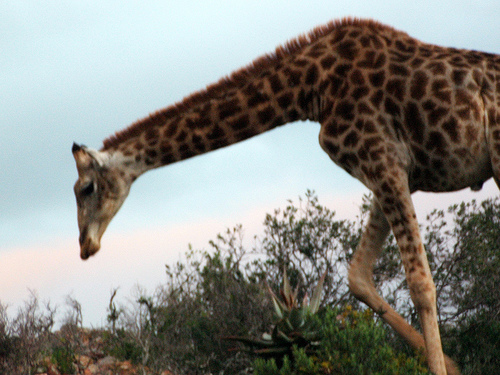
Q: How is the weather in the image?
A: It is cloudy.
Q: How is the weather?
A: It is cloudy.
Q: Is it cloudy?
A: Yes, it is cloudy.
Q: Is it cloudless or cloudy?
A: It is cloudy.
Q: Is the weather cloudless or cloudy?
A: It is cloudy.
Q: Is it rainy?
A: No, it is cloudy.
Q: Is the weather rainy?
A: No, it is cloudy.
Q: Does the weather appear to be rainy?
A: No, it is cloudy.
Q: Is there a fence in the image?
A: No, there are no fences.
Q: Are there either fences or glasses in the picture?
A: No, there are no fences or glasses.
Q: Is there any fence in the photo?
A: No, there are no fences.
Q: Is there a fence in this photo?
A: No, there are no fences.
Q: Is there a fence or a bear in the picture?
A: No, there are no fences or bears.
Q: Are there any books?
A: No, there are no books.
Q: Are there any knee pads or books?
A: No, there are no books or knee pads.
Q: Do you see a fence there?
A: No, there are no fences.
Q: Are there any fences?
A: No, there are no fences.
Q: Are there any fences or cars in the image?
A: No, there are no fences or cars.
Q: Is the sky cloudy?
A: Yes, the sky is cloudy.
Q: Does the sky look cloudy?
A: Yes, the sky is cloudy.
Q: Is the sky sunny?
A: No, the sky is cloudy.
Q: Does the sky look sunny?
A: No, the sky is cloudy.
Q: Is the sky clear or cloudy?
A: The sky is cloudy.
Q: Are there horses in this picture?
A: No, there are no horses.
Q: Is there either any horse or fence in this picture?
A: No, there are no horses or fences.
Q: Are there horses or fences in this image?
A: No, there are no horses or fences.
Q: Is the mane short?
A: Yes, the mane is short.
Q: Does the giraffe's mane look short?
A: Yes, the mane is short.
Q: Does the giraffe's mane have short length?
A: Yes, the mane is short.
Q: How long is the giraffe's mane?
A: The mane is short.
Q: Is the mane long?
A: No, the mane is short.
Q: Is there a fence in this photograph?
A: No, there are no fences.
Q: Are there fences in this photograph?
A: No, there are no fences.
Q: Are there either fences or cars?
A: No, there are no fences or cars.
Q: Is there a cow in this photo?
A: No, there are no cows.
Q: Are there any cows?
A: No, there are no cows.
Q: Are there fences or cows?
A: No, there are no cows or fences.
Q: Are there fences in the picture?
A: No, there are no fences.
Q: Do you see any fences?
A: No, there are no fences.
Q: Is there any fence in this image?
A: No, there are no fences.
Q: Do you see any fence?
A: No, there are no fences.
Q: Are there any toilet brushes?
A: No, there are no toilet brushes.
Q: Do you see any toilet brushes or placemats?
A: No, there are no toilet brushes or placemats.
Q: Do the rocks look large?
A: Yes, the rocks are large.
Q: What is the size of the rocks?
A: The rocks are large.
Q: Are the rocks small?
A: No, the rocks are large.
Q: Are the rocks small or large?
A: The rocks are large.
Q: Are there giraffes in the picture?
A: Yes, there is a giraffe.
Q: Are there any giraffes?
A: Yes, there is a giraffe.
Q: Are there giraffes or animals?
A: Yes, there is a giraffe.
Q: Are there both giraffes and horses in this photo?
A: No, there is a giraffe but no horses.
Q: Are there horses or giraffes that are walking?
A: Yes, the giraffe is walking.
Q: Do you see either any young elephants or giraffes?
A: Yes, there is a young giraffe.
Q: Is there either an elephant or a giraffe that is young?
A: Yes, the giraffe is young.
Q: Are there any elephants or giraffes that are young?
A: Yes, the giraffe is young.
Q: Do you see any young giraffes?
A: Yes, there is a young giraffe.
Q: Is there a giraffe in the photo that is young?
A: Yes, there is a giraffe that is young.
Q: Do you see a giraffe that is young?
A: Yes, there is a giraffe that is young.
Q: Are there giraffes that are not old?
A: Yes, there is an young giraffe.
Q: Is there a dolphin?
A: No, there are no dolphins.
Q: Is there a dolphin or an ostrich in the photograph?
A: No, there are no dolphins or ostriches.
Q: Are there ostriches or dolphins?
A: No, there are no dolphins or ostriches.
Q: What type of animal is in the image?
A: The animal is a giraffe.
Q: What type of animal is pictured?
A: The animal is a giraffe.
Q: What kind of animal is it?
A: The animal is a giraffe.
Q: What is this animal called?
A: This is a giraffe.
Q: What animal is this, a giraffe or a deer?
A: This is a giraffe.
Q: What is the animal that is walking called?
A: The animal is a giraffe.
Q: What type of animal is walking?
A: The animal is a giraffe.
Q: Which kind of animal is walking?
A: The animal is a giraffe.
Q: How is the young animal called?
A: The animal is a giraffe.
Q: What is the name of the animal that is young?
A: The animal is a giraffe.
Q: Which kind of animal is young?
A: The animal is a giraffe.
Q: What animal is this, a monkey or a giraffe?
A: This is a giraffe.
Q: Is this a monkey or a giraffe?
A: This is a giraffe.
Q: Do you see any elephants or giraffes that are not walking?
A: No, there is a giraffe but it is walking.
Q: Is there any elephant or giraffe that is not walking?
A: No, there is a giraffe but it is walking.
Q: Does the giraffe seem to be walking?
A: Yes, the giraffe is walking.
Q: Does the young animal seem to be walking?
A: Yes, the giraffe is walking.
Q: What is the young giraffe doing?
A: The giraffe is walking.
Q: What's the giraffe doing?
A: The giraffe is walking.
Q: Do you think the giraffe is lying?
A: No, the giraffe is walking.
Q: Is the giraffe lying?
A: No, the giraffe is walking.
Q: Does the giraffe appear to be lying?
A: No, the giraffe is walking.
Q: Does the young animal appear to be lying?
A: No, the giraffe is walking.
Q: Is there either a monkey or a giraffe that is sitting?
A: No, there is a giraffe but it is walking.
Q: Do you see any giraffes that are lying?
A: No, there is a giraffe but it is walking.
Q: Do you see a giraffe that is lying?
A: No, there is a giraffe but it is walking.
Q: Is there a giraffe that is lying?
A: No, there is a giraffe but it is walking.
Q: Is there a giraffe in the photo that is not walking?
A: No, there is a giraffe but it is walking.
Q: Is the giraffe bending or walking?
A: The giraffe is walking.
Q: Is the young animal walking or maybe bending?
A: The giraffe is walking.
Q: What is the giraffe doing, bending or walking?
A: The giraffe is walking.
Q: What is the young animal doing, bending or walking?
A: The giraffe is walking.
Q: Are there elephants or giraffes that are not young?
A: No, there is a giraffe but it is young.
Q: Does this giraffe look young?
A: Yes, the giraffe is young.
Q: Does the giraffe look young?
A: Yes, the giraffe is young.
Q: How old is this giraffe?
A: The giraffe is young.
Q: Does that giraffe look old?
A: No, the giraffe is young.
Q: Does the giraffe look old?
A: No, the giraffe is young.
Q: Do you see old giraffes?
A: No, there is a giraffe but it is young.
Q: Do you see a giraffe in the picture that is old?
A: No, there is a giraffe but it is young.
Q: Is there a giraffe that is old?
A: No, there is a giraffe but it is young.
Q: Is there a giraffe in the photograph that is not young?
A: No, there is a giraffe but it is young.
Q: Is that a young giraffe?
A: Yes, that is a young giraffe.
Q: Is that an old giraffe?
A: No, that is a young giraffe.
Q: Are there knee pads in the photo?
A: No, there are no knee pads.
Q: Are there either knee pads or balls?
A: No, there are no knee pads or balls.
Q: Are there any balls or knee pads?
A: No, there are no knee pads or balls.